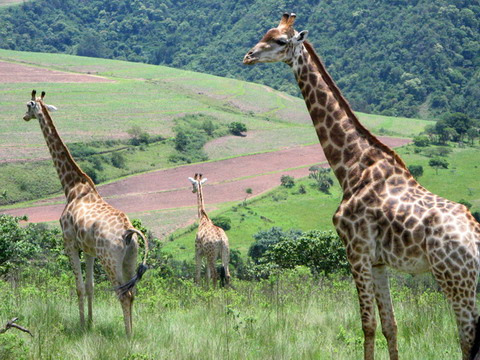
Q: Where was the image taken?
A: It was taken at the field.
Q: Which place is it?
A: It is a field.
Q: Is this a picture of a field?
A: Yes, it is showing a field.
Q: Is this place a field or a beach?
A: It is a field.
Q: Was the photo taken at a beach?
A: No, the picture was taken in a field.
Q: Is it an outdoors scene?
A: Yes, it is outdoors.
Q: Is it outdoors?
A: Yes, it is outdoors.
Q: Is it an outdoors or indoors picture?
A: It is outdoors.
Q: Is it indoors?
A: No, it is outdoors.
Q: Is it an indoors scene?
A: No, it is outdoors.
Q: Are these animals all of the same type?
A: Yes, all the animals are giraffes.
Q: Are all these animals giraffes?
A: Yes, all the animals are giraffes.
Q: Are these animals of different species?
A: No, all the animals are giraffes.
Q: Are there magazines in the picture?
A: No, there are no magazines.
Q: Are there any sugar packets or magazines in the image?
A: No, there are no magazines or sugar packets.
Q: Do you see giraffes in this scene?
A: Yes, there is a giraffe.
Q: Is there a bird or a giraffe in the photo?
A: Yes, there is a giraffe.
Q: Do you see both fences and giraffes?
A: No, there is a giraffe but no fences.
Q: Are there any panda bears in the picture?
A: No, there are no panda bears.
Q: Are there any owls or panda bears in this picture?
A: No, there are no panda bears or owls.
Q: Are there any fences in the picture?
A: No, there are no fences.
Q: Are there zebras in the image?
A: No, there are no zebras.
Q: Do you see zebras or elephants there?
A: No, there are no zebras or elephants.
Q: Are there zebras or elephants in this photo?
A: No, there are no zebras or elephants.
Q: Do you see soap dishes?
A: No, there are no soap dishes.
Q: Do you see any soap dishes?
A: No, there are no soap dishes.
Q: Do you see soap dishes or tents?
A: No, there are no soap dishes or tents.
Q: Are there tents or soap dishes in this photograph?
A: No, there are no soap dishes or tents.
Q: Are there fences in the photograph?
A: No, there are no fences.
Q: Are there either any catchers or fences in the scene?
A: No, there are no fences or catchers.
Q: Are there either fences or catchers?
A: No, there are no fences or catchers.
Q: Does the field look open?
A: Yes, the field is open.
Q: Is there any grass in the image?
A: Yes, there is grass.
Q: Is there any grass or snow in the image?
A: Yes, there is grass.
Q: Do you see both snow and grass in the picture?
A: No, there is grass but no snow.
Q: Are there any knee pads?
A: No, there are no knee pads.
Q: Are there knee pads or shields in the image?
A: No, there are no knee pads or shields.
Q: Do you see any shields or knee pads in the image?
A: No, there are no knee pads or shields.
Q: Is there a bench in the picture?
A: No, there are no benches.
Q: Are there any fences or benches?
A: No, there are no benches or fences.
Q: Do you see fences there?
A: No, there are no fences.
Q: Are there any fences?
A: No, there are no fences.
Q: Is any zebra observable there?
A: No, there are no zebras.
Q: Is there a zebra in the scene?
A: No, there are no zebras.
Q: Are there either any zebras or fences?
A: No, there are no zebras or fences.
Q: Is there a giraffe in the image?
A: Yes, there is a giraffe.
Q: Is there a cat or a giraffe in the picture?
A: Yes, there is a giraffe.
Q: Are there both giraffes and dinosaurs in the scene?
A: No, there is a giraffe but no dinosaurs.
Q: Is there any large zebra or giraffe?
A: Yes, there is a large giraffe.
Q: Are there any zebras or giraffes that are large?
A: Yes, the giraffe is large.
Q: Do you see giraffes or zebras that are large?
A: Yes, the giraffe is large.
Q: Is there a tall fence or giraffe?
A: Yes, there is a tall giraffe.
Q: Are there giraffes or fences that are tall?
A: Yes, the giraffe is tall.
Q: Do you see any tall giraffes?
A: Yes, there is a tall giraffe.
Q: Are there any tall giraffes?
A: Yes, there is a tall giraffe.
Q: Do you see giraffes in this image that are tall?
A: Yes, there is a giraffe that is tall.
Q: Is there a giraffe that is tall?
A: Yes, there is a giraffe that is tall.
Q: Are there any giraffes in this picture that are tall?
A: Yes, there is a giraffe that is tall.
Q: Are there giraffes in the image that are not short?
A: Yes, there is a tall giraffe.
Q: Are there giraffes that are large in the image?
A: Yes, there is a large giraffe.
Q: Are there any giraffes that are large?
A: Yes, there is a giraffe that is large.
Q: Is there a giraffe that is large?
A: Yes, there is a giraffe that is large.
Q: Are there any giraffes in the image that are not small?
A: Yes, there is a large giraffe.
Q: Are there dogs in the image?
A: No, there are no dogs.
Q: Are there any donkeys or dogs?
A: No, there are no dogs or donkeys.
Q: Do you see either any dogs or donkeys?
A: No, there are no dogs or donkeys.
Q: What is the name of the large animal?
A: The animal is a giraffe.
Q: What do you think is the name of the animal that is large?
A: The animal is a giraffe.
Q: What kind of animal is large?
A: The animal is a giraffe.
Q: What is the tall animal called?
A: The animal is a giraffe.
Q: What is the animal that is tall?
A: The animal is a giraffe.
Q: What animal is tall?
A: The animal is a giraffe.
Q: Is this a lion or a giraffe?
A: This is a giraffe.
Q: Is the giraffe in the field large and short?
A: No, the giraffe is large but tall.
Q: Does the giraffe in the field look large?
A: Yes, the giraffe is large.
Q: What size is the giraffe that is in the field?
A: The giraffe is large.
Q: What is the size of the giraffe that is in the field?
A: The giraffe is large.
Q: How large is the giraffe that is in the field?
A: The giraffe is large.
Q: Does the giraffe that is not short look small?
A: No, the giraffe is large.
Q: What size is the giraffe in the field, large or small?
A: The giraffe is large.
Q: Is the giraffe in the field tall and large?
A: Yes, the giraffe is tall and large.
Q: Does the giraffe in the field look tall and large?
A: Yes, the giraffe is tall and large.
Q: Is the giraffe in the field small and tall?
A: No, the giraffe is tall but large.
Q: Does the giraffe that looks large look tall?
A: Yes, the giraffe is tall.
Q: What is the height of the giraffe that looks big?
A: The giraffe is tall.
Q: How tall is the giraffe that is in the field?
A: The giraffe is tall.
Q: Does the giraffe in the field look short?
A: No, the giraffe is tall.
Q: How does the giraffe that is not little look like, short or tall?
A: The giraffe is tall.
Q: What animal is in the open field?
A: The animal is a giraffe.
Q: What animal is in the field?
A: The animal is a giraffe.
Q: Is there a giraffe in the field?
A: Yes, there is a giraffe in the field.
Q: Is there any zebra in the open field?
A: No, there is a giraffe in the field.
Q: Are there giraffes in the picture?
A: Yes, there is a giraffe.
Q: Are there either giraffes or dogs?
A: Yes, there is a giraffe.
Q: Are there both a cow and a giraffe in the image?
A: No, there is a giraffe but no cows.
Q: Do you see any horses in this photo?
A: No, there are no horses.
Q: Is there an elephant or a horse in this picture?
A: No, there are no horses or elephants.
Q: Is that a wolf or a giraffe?
A: That is a giraffe.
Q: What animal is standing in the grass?
A: The giraffe is standing in the grass.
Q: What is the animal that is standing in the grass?
A: The animal is a giraffe.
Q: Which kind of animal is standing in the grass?
A: The animal is a giraffe.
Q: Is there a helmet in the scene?
A: No, there are no helmets.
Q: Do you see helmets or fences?
A: No, there are no helmets or fences.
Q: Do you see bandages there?
A: No, there are no bandages.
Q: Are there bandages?
A: No, there are no bandages.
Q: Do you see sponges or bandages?
A: No, there are no bandages or sponges.